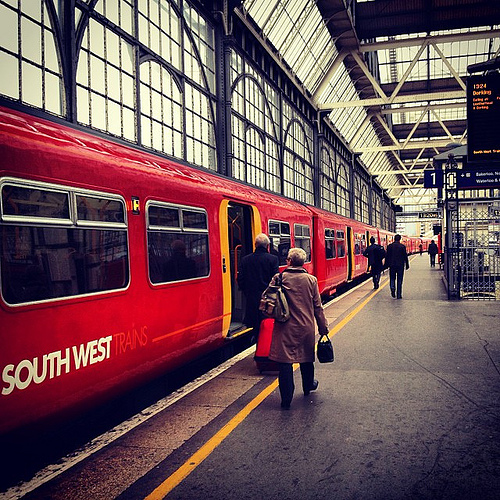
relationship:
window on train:
[149, 194, 237, 266] [2, 105, 388, 363]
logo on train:
[6, 323, 126, 386] [2, 105, 388, 363]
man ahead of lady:
[229, 216, 283, 350] [257, 246, 331, 406]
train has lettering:
[2, 105, 388, 363] [1, 342, 126, 400]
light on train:
[122, 191, 163, 252] [2, 105, 388, 363]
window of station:
[74, 35, 249, 156] [137, 31, 491, 258]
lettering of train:
[1, 342, 126, 400] [2, 105, 388, 363]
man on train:
[229, 216, 283, 350] [2, 105, 388, 363]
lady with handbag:
[257, 246, 331, 406] [317, 335, 335, 365]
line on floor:
[137, 408, 262, 474] [229, 234, 474, 442]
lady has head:
[257, 246, 331, 406] [278, 243, 315, 268]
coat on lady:
[258, 268, 317, 360] [257, 246, 331, 406]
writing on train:
[1, 342, 126, 400] [2, 105, 388, 363]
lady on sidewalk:
[257, 246, 331, 406] [225, 224, 423, 487]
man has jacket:
[229, 216, 283, 350] [238, 261, 304, 305]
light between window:
[122, 191, 163, 252] [149, 194, 237, 266]